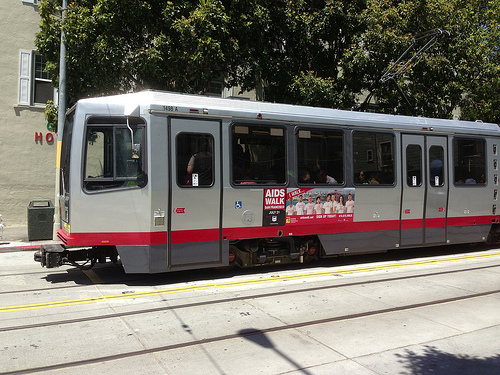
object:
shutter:
[15, 46, 35, 110]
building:
[0, 0, 486, 255]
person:
[186, 138, 213, 186]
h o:
[35, 132, 54, 142]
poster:
[263, 186, 355, 226]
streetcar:
[37, 86, 497, 271]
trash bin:
[27, 200, 55, 241]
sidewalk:
[6, 233, 100, 246]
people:
[286, 196, 296, 217]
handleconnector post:
[33, 247, 118, 269]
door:
[167, 115, 223, 267]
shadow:
[398, 340, 498, 372]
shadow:
[2, 250, 495, 372]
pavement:
[0, 245, 495, 372]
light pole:
[53, 4, 69, 242]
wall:
[214, 88, 276, 132]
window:
[87, 120, 144, 185]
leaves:
[43, 3, 485, 115]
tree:
[40, 0, 486, 102]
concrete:
[0, 253, 496, 372]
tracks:
[1, 261, 483, 370]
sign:
[191, 173, 198, 187]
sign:
[413, 176, 417, 186]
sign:
[435, 176, 440, 187]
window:
[292, 125, 350, 186]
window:
[176, 131, 215, 188]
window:
[227, 121, 291, 185]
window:
[351, 130, 398, 186]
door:
[398, 131, 428, 248]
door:
[426, 131, 451, 247]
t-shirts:
[286, 204, 296, 215]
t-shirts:
[295, 201, 306, 218]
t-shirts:
[303, 201, 316, 218]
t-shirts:
[314, 204, 323, 216]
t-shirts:
[343, 200, 354, 213]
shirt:
[185, 151, 214, 183]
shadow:
[235, 328, 311, 375]